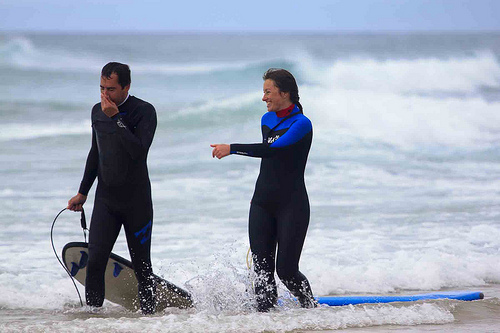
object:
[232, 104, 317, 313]
wetsuit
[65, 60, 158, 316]
man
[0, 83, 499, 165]
wave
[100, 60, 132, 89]
hair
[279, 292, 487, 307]
surfboard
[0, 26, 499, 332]
water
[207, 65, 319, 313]
person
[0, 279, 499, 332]
beach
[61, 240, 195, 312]
body board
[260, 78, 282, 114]
face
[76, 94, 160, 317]
wetsuit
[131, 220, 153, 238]
stripes